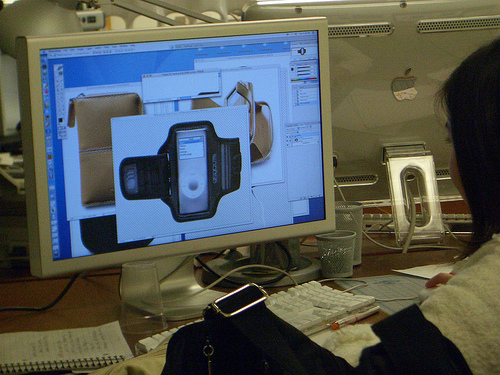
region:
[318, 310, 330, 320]
white key on keyboard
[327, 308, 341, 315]
white key on keyboard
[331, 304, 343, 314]
white key on keyboard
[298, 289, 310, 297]
white key on keyboard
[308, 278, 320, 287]
white key on keyboard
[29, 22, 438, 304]
this is a computer screen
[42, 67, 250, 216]
the computer is on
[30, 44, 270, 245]
the monitor is on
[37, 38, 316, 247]
the monitor is large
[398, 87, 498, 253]
the lady is asian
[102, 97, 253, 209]
this is an ipod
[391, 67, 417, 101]
silver apple on back of monitor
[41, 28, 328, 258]
several images loaded up on screen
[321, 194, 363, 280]
beige wire cups on screen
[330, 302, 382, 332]
white and orange pen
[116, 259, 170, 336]
plastic cup upside down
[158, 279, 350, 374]
black purse on desk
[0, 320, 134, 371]
spiral bound notebook on desk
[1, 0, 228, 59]
desk lamp with long arm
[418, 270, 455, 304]
person has mouse in hand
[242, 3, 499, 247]
an Apple Cinema display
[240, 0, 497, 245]
a computer monitor display back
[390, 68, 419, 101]
Apple computer corporate logo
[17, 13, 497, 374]
a woman using a Macintosh computer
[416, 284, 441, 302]
an Apple Mighty Mouse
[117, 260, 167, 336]
an upside down plastic cup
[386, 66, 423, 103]
Shiny Apple logo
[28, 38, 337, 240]
Computer monitor with windows open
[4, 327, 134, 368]
White spiral notebook with writing on it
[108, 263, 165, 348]
Clear plastic cup upside-down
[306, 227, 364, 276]
Small metal cup with items inside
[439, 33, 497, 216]
Profile of woman with black hair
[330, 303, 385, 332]
Orange and white pen on desk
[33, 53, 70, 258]
Computer sidebar with icons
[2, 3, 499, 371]
a scene at a computer station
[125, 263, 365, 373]
a black bag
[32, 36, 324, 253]
a program is running on the screen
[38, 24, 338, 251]
the screen is bluish in color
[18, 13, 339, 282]
the monitor frame is made of metal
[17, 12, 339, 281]
the monitor frame is grey in color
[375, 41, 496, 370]
a woman is looking at the screen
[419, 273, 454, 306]
the woman is using the mouse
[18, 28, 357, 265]
computer screen showing a cell phone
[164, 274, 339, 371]
black purse laying on the desk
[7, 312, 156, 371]
a notebook with writing on it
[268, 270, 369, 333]
right side of a computer keyboard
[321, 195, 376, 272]
paper clip and pen holders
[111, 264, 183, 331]
clear cup on the desk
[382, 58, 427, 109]
apple logo on the computer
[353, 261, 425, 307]
gray mousepad on the desk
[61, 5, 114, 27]
a silver plug in the distance